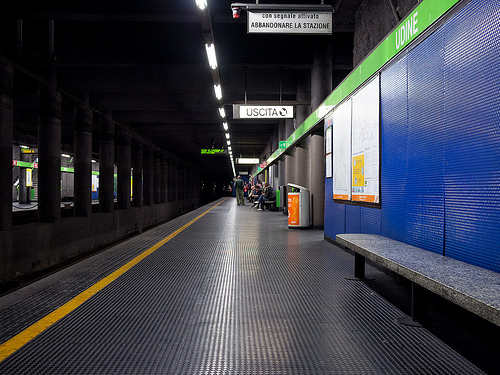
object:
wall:
[399, 80, 484, 146]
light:
[214, 84, 223, 100]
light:
[195, 0, 208, 10]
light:
[225, 133, 230, 139]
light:
[228, 146, 232, 150]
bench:
[334, 233, 500, 327]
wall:
[443, 178, 482, 241]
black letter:
[247, 108, 287, 116]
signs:
[247, 11, 333, 34]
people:
[234, 175, 277, 211]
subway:
[0, 60, 204, 289]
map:
[332, 75, 380, 204]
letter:
[251, 22, 330, 29]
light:
[223, 122, 229, 131]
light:
[219, 108, 227, 119]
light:
[205, 43, 218, 69]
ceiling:
[53, 0, 397, 185]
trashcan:
[287, 183, 311, 229]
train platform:
[1, 197, 498, 367]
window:
[60, 156, 75, 220]